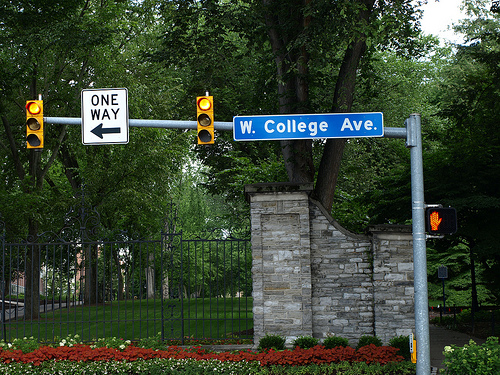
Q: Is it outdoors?
A: Yes, it is outdoors.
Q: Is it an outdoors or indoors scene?
A: It is outdoors.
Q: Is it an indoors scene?
A: No, it is outdoors.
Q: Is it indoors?
A: No, it is outdoors.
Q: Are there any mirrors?
A: No, there are no mirrors.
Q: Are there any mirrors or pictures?
A: No, there are no mirrors or pictures.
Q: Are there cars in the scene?
A: No, there are no cars.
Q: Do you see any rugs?
A: No, there are no rugs.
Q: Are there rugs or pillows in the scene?
A: No, there are no rugs or pillows.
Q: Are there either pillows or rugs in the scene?
A: No, there are no rugs or pillows.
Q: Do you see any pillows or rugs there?
A: No, there are no rugs or pillows.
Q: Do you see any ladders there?
A: No, there are no ladders.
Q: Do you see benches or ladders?
A: No, there are no ladders or benches.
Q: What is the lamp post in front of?
A: The lamp post is in front of the flowers.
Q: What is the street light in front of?
A: The lamp post is in front of the flowers.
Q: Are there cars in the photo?
A: No, there are no cars.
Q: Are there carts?
A: No, there are no carts.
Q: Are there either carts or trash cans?
A: No, there are no carts or trash cans.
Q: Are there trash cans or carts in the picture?
A: No, there are no carts or trash cans.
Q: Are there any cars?
A: No, there are no cars.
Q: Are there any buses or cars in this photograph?
A: No, there are no cars or buses.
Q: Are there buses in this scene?
A: No, there are no buses.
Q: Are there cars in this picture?
A: No, there are no cars.